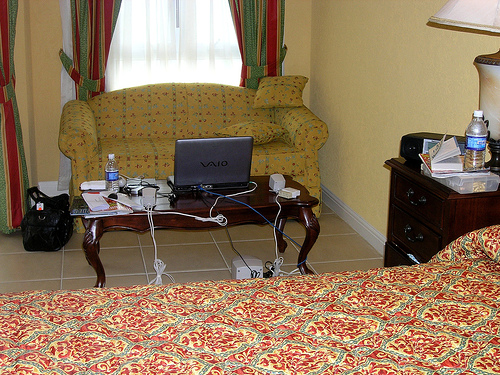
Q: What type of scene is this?
A: Indoor.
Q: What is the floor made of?
A: Tiles.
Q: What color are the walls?
A: Cream.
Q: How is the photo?
A: Clear.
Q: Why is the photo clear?
A: Room is well lit.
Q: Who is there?
A: No one.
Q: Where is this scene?
A: Bedroom.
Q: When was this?
A: Daytime.